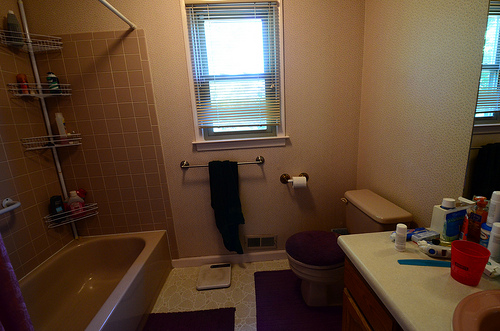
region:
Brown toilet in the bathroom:
[281, 185, 411, 293]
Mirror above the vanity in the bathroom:
[453, 0, 496, 247]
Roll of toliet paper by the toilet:
[276, 168, 310, 194]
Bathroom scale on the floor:
[187, 258, 234, 294]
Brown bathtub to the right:
[0, 226, 172, 330]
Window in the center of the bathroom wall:
[176, 1, 290, 155]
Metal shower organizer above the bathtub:
[1, 0, 102, 240]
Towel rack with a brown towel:
[176, 151, 272, 261]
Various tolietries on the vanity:
[387, 178, 497, 289]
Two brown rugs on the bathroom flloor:
[135, 261, 373, 329]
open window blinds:
[186, 3, 286, 133]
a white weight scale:
[192, 261, 235, 292]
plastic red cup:
[447, 237, 493, 289]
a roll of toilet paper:
[285, 171, 310, 191]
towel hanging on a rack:
[172, 152, 274, 259]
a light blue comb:
[395, 254, 449, 269]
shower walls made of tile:
[3, 25, 184, 280]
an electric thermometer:
[414, 238, 451, 260]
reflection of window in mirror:
[455, 4, 499, 175]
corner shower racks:
[5, 5, 109, 247]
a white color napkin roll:
[281, 170, 311, 188]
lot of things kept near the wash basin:
[402, 192, 499, 277]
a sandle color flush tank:
[334, 189, 401, 232]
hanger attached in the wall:
[174, 152, 266, 174]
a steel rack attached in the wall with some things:
[4, 13, 119, 233]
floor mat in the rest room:
[253, 269, 340, 329]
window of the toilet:
[186, 3, 287, 150]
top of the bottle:
[443, 198, 454, 207]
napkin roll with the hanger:
[276, 172, 313, 190]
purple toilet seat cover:
[285, 231, 342, 263]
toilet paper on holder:
[290, 173, 306, 187]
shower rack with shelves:
[0, 3, 96, 238]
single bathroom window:
[188, 5, 283, 139]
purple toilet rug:
[252, 268, 333, 329]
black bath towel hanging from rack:
[207, 160, 250, 255]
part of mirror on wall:
[458, 0, 498, 207]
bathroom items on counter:
[391, 189, 498, 269]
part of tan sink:
[454, 288, 496, 329]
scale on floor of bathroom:
[193, 263, 232, 288]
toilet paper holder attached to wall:
[280, 168, 312, 188]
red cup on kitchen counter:
[440, 233, 485, 287]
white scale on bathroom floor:
[190, 256, 232, 294]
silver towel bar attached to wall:
[168, 153, 268, 164]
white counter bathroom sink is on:
[335, 220, 493, 329]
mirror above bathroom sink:
[456, 10, 498, 257]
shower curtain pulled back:
[0, 241, 47, 330]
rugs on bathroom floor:
[149, 264, 351, 330]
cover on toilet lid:
[285, 227, 342, 264]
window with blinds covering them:
[180, 7, 281, 127]